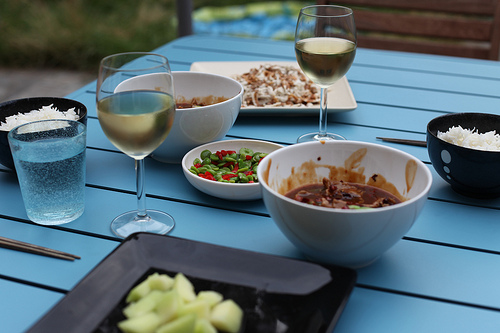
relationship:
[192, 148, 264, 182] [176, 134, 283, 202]
vegetables in a bowl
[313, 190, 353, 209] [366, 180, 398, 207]
pork in sauce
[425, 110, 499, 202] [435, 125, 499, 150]
bowl filled with rice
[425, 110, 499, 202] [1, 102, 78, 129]
bowl filled with rice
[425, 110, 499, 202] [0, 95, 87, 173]
bowl filled with bowl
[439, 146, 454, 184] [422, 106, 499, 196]
circles on a bowl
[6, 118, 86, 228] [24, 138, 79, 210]
glass of water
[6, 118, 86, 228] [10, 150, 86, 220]
glass of water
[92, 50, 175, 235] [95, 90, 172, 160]
glass of wine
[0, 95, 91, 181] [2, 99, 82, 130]
bowl of rice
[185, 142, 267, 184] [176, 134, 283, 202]
peppers in a bowl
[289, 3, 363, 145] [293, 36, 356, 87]
glass of wine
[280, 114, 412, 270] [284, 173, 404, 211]
white bowl with gravy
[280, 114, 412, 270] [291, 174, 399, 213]
white bowl with meat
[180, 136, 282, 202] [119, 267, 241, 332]
bowl with food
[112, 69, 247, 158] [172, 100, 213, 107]
bowl with beans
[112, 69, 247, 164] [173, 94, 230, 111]
bowl with food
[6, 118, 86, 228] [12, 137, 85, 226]
glass with water